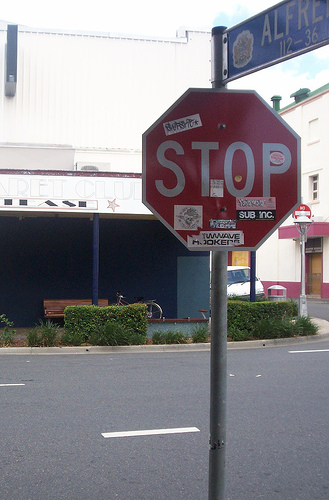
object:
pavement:
[57, 361, 317, 413]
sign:
[139, 87, 298, 260]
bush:
[137, 303, 145, 315]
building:
[14, 145, 136, 301]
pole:
[90, 217, 100, 308]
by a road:
[246, 348, 313, 372]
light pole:
[297, 247, 309, 323]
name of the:
[10, 178, 138, 195]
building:
[16, 72, 141, 133]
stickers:
[154, 118, 288, 208]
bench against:
[44, 295, 107, 311]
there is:
[95, 285, 167, 319]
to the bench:
[26, 292, 115, 322]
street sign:
[215, 0, 327, 79]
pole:
[208, 271, 226, 485]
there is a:
[248, 251, 258, 308]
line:
[94, 426, 203, 439]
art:
[219, 205, 229, 216]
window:
[230, 271, 256, 281]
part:
[273, 287, 278, 291]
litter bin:
[267, 282, 288, 298]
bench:
[41, 295, 110, 319]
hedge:
[231, 300, 304, 336]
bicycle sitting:
[134, 295, 146, 305]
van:
[226, 268, 266, 299]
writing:
[238, 210, 256, 219]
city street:
[133, 11, 324, 347]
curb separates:
[300, 326, 327, 342]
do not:
[294, 201, 315, 221]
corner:
[313, 299, 329, 348]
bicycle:
[108, 293, 163, 319]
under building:
[19, 215, 170, 293]